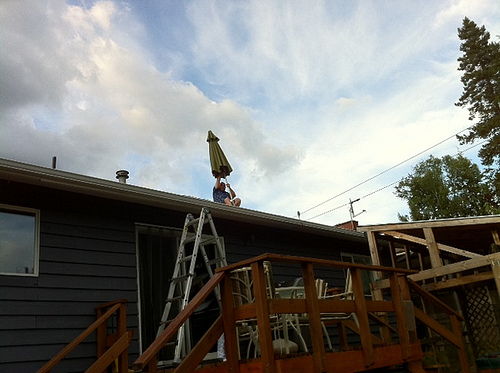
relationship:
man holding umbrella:
[207, 171, 240, 208] [202, 127, 237, 182]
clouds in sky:
[3, 2, 130, 118] [2, 2, 498, 219]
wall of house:
[2, 191, 155, 369] [0, 158, 431, 369]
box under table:
[264, 334, 303, 356] [248, 279, 313, 306]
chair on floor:
[226, 267, 304, 351] [208, 342, 432, 373]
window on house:
[1, 200, 45, 279] [0, 158, 431, 369]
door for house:
[175, 236, 223, 361] [0, 158, 431, 369]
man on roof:
[207, 171, 240, 208] [5, 157, 371, 243]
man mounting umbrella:
[207, 171, 240, 208] [202, 127, 237, 182]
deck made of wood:
[89, 260, 460, 372] [340, 355, 350, 357]